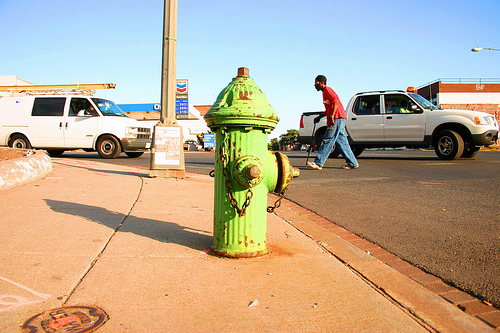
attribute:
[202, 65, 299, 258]
hydrant — green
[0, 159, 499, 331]
sidewalk — cement, dry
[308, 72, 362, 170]
person — walking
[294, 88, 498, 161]
vehicle — white, turning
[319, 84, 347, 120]
shirt — red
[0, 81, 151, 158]
van — white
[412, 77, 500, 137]
building — brown